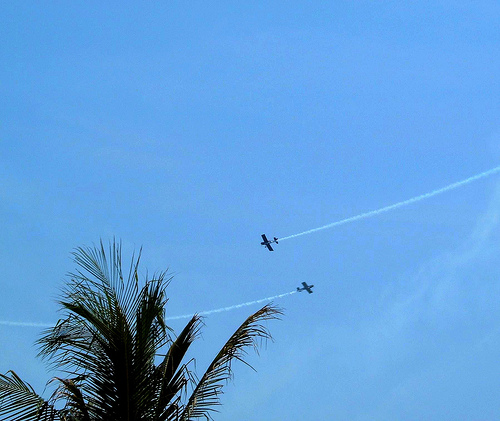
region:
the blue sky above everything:
[3, 6, 499, 413]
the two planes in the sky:
[260, 232, 312, 299]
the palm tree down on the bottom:
[3, 244, 281, 419]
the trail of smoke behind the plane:
[279, 157, 499, 260]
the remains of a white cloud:
[391, 199, 498, 334]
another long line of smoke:
[2, 284, 299, 331]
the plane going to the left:
[260, 230, 279, 250]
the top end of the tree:
[71, 235, 146, 291]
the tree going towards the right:
[292, 280, 314, 296]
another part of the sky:
[365, 187, 494, 387]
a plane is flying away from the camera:
[297, 273, 319, 298]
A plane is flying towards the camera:
[253, 225, 287, 261]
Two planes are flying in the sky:
[240, 212, 351, 307]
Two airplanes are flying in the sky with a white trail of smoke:
[237, 178, 409, 322]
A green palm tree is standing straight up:
[7, 237, 247, 395]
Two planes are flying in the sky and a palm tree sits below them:
[1, 220, 347, 411]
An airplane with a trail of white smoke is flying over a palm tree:
[62, 220, 294, 273]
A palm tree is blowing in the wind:
[5, 262, 284, 415]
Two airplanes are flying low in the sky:
[252, 207, 350, 312]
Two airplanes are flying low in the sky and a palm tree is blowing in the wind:
[11, 225, 321, 410]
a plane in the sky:
[252, 224, 285, 259]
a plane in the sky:
[289, 276, 324, 299]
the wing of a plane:
[259, 232, 269, 242]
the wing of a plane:
[266, 243, 273, 252]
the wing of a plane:
[301, 280, 308, 286]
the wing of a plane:
[307, 287, 313, 295]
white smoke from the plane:
[278, 165, 497, 242]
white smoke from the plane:
[3, 285, 295, 333]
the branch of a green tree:
[177, 302, 269, 417]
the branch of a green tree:
[158, 304, 205, 409]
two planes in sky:
[254, 228, 331, 300]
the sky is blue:
[15, 7, 497, 191]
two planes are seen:
[249, 220, 334, 317]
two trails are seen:
[203, 207, 383, 335]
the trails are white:
[168, 207, 370, 323]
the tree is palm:
[52, 256, 247, 419]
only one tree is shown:
[66, 250, 237, 419]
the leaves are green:
[62, 262, 269, 419]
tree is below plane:
[98, 191, 312, 415]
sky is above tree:
[49, 155, 223, 417]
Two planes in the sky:
[254, 225, 320, 300]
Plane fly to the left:
[253, 226, 284, 256]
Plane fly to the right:
[293, 274, 321, 302]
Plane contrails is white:
[275, 165, 496, 258]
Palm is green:
[0, 221, 280, 412]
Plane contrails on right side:
[280, 160, 496, 246]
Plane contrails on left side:
[0, 269, 325, 336]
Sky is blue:
[5, 4, 496, 419]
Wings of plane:
[301, 279, 313, 299]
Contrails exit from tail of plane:
[270, 229, 305, 247]